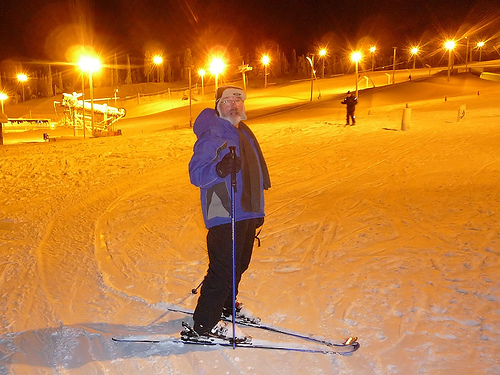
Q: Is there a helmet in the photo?
A: No, there are no helmets.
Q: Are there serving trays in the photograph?
A: No, there are no serving trays.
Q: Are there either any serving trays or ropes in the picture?
A: No, there are no serving trays or ropes.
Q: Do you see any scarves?
A: Yes, there is a scarf.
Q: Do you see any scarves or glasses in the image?
A: Yes, there is a scarf.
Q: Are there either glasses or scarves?
A: Yes, there is a scarf.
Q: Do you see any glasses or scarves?
A: Yes, there is a scarf.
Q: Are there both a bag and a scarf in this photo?
A: No, there is a scarf but no bags.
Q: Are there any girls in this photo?
A: No, there are no girls.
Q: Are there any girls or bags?
A: No, there are no girls or bags.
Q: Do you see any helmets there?
A: No, there are no helmets.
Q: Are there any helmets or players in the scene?
A: No, there are no helmets or players.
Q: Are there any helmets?
A: No, there are no helmets.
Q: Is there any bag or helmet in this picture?
A: No, there are no helmets or bags.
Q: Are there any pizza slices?
A: No, there are no pizza slices.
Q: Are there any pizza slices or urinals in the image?
A: No, there are no pizza slices or urinals.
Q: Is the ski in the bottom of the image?
A: Yes, the ski is in the bottom of the image.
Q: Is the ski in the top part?
A: No, the ski is in the bottom of the image.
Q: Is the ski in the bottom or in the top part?
A: The ski is in the bottom of the image.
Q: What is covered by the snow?
A: The ski is covered by the snow.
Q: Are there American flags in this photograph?
A: No, there are no American flags.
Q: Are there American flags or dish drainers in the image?
A: No, there are no American flags or dish drainers.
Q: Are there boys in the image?
A: No, there are no boys.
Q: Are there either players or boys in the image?
A: No, there are no boys or players.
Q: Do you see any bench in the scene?
A: No, there are no benches.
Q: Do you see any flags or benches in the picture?
A: No, there are no benches or flags.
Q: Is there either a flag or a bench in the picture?
A: No, there are no benches or flags.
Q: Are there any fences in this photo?
A: Yes, there is a fence.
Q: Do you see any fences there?
A: Yes, there is a fence.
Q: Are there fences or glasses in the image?
A: Yes, there is a fence.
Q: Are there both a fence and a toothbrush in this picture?
A: No, there is a fence but no toothbrushes.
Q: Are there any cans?
A: No, there are no cans.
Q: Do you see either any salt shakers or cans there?
A: No, there are no cans or salt shakers.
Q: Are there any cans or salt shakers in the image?
A: No, there are no cans or salt shakers.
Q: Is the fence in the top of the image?
A: Yes, the fence is in the top of the image.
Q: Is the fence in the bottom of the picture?
A: No, the fence is in the top of the image.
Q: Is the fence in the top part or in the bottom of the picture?
A: The fence is in the top of the image.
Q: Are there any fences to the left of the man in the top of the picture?
A: Yes, there is a fence to the left of the man.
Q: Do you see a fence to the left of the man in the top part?
A: Yes, there is a fence to the left of the man.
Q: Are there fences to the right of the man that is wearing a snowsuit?
A: No, the fence is to the left of the man.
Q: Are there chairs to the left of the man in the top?
A: No, there is a fence to the left of the man.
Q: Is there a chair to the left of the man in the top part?
A: No, there is a fence to the left of the man.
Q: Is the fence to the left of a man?
A: Yes, the fence is to the left of a man.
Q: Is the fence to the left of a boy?
A: No, the fence is to the left of a man.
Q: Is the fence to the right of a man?
A: No, the fence is to the left of a man.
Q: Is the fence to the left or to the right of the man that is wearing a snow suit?
A: The fence is to the left of the man.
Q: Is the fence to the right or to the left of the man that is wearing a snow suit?
A: The fence is to the left of the man.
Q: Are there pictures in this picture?
A: No, there are no pictures.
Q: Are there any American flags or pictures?
A: No, there are no pictures or American flags.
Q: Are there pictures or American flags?
A: No, there are no pictures or American flags.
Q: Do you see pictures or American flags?
A: No, there are no pictures or American flags.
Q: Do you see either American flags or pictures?
A: No, there are no pictures or American flags.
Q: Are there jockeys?
A: No, there are no jockeys.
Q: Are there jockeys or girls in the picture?
A: No, there are no jockeys or girls.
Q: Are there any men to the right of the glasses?
A: Yes, there is a man to the right of the glasses.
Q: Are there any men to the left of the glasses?
A: No, the man is to the right of the glasses.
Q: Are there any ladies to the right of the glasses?
A: No, there is a man to the right of the glasses.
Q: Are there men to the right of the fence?
A: Yes, there is a man to the right of the fence.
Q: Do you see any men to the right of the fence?
A: Yes, there is a man to the right of the fence.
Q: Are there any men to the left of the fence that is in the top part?
A: No, the man is to the right of the fence.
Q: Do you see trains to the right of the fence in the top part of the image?
A: No, there is a man to the right of the fence.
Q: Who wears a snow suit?
A: The man wears a snow suit.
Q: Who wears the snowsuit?
A: The man wears a snow suit.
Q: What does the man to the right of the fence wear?
A: The man wears a snowsuit.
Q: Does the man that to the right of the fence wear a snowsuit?
A: Yes, the man wears a snowsuit.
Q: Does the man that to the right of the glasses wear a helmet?
A: No, the man wears a snowsuit.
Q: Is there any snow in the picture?
A: Yes, there is snow.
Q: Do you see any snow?
A: Yes, there is snow.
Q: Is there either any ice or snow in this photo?
A: Yes, there is snow.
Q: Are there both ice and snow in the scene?
A: No, there is snow but no ice.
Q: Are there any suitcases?
A: No, there are no suitcases.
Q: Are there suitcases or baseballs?
A: No, there are no suitcases or baseballs.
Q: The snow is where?
A: The snow is on the ground.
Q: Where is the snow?
A: The snow is on the ground.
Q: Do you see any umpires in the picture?
A: No, there are no umpires.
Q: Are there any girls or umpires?
A: No, there are no umpires or girls.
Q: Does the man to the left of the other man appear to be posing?
A: Yes, the man is posing.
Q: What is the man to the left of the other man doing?
A: The man is posing.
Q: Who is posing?
A: The man is posing.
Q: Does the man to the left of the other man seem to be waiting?
A: No, the man is posing.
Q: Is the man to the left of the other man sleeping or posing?
A: The man is posing.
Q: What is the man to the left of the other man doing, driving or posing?
A: The man is posing.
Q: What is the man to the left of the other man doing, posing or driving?
A: The man is posing.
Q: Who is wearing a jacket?
A: The man is wearing a jacket.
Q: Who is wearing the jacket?
A: The man is wearing a jacket.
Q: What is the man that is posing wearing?
A: The man is wearing a jacket.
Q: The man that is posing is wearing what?
A: The man is wearing a jacket.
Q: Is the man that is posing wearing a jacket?
A: Yes, the man is wearing a jacket.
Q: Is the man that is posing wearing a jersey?
A: No, the man is wearing a jacket.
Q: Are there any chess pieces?
A: No, there are no chess pieces.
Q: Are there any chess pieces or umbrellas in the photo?
A: No, there are no chess pieces or umbrellas.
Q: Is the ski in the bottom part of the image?
A: Yes, the ski is in the bottom of the image.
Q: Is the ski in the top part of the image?
A: No, the ski is in the bottom of the image.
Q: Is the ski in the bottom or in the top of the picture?
A: The ski is in the bottom of the image.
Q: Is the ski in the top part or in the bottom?
A: The ski is in the bottom of the image.